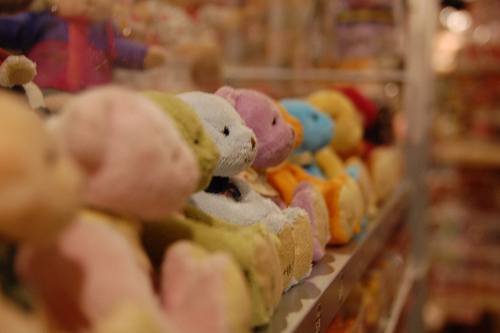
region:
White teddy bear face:
[205, 83, 255, 178]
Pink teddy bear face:
[245, 87, 295, 162]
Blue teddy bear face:
[290, 96, 331, 146]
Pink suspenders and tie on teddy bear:
[30, 15, 115, 85]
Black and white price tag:
[330, 272, 346, 302]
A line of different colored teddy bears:
[0, 75, 401, 325]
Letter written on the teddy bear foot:
[280, 255, 295, 277]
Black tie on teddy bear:
[210, 175, 240, 201]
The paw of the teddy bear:
[140, 40, 165, 70]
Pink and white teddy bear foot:
[293, 183, 333, 254]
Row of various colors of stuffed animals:
[0, 53, 402, 331]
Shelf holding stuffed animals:
[252, 185, 409, 332]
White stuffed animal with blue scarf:
[172, 89, 314, 294]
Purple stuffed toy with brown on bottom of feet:
[211, 84, 333, 263]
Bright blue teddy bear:
[274, 96, 369, 236]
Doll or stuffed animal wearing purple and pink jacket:
[0, 0, 168, 95]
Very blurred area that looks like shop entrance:
[406, 0, 498, 330]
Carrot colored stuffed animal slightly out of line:
[265, 98, 366, 246]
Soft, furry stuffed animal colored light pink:
[14, 83, 250, 331]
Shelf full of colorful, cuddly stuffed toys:
[2, 85, 403, 330]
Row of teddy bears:
[1, 84, 415, 331]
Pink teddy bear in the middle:
[213, 87, 329, 266]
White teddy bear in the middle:
[174, 91, 314, 281]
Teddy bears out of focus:
[1, 92, 240, 330]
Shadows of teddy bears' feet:
[267, 248, 355, 327]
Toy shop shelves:
[2, 86, 431, 328]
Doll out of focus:
[30, 0, 170, 87]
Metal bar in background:
[408, 4, 438, 207]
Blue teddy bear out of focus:
[276, 99, 366, 239]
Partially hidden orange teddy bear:
[263, 97, 352, 247]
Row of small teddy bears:
[1, 50, 380, 330]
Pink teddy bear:
[212, 83, 330, 263]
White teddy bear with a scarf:
[174, 88, 314, 291]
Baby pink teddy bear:
[41, 85, 248, 330]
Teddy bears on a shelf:
[0, 0, 430, 332]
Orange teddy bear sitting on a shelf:
[255, 95, 362, 247]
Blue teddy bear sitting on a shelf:
[278, 98, 371, 241]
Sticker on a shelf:
[312, 269, 347, 331]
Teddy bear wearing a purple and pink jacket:
[1, 0, 166, 92]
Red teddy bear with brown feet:
[330, 85, 395, 200]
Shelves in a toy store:
[7, 0, 494, 328]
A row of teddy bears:
[38, 77, 411, 308]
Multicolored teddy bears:
[70, 74, 379, 233]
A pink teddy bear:
[35, 66, 192, 330]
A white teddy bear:
[182, 77, 257, 182]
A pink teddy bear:
[230, 79, 319, 174]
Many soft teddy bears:
[0, 67, 460, 316]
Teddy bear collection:
[40, 49, 428, 324]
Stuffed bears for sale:
[7, 55, 427, 310]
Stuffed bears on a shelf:
[20, 17, 444, 308]